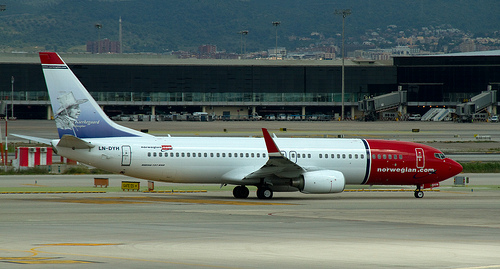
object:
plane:
[36, 51, 462, 200]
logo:
[377, 166, 436, 173]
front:
[361, 138, 463, 189]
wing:
[241, 127, 307, 180]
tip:
[261, 127, 281, 153]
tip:
[37, 52, 155, 138]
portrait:
[52, 90, 100, 137]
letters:
[98, 146, 120, 151]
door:
[122, 145, 132, 167]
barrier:
[10, 146, 53, 167]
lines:
[32, 195, 305, 205]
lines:
[0, 247, 224, 269]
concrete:
[0, 186, 500, 269]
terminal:
[37, 52, 154, 181]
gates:
[404, 82, 445, 102]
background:
[0, 0, 500, 126]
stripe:
[360, 138, 370, 185]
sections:
[0, 135, 500, 269]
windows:
[318, 153, 403, 159]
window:
[147, 151, 152, 158]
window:
[153, 152, 157, 157]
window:
[158, 152, 163, 158]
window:
[164, 152, 169, 157]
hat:
[56, 91, 89, 115]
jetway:
[356, 85, 410, 121]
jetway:
[455, 84, 497, 122]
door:
[289, 150, 297, 164]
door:
[281, 150, 288, 158]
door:
[415, 147, 426, 168]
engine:
[290, 170, 346, 194]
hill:
[0, 0, 498, 53]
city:
[87, 24, 500, 62]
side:
[345, 137, 464, 189]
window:
[175, 152, 180, 158]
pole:
[340, 11, 345, 120]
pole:
[273, 19, 279, 58]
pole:
[240, 28, 243, 59]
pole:
[118, 14, 123, 57]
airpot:
[0, 49, 500, 269]